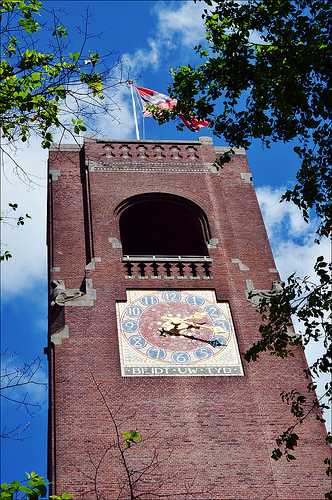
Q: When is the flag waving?
A: Daytime.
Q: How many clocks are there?
A: One.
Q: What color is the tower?
A: Red.